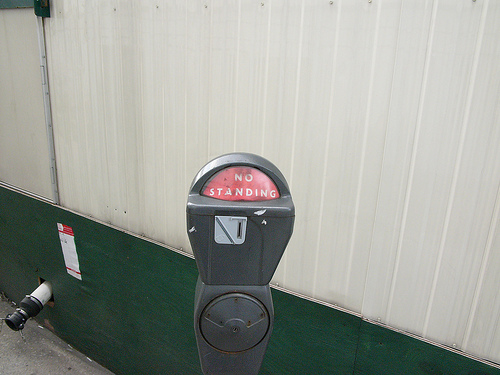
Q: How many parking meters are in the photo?
A: One.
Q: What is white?
A: Wall.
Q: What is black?
A: Parking meter.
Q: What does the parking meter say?
A: "NO STANDING".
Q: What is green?
A: Bottom part of wall.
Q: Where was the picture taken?
A: Next to building.